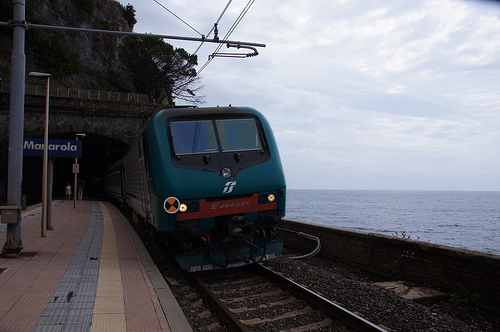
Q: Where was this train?
A: Next to the water.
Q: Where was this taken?
A: At a train station.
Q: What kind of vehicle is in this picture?
A: A train.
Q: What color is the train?
A: Teal and red.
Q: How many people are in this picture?
A: None.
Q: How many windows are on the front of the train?
A: Two.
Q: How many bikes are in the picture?
A: None.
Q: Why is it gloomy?
A: It's cloudy.